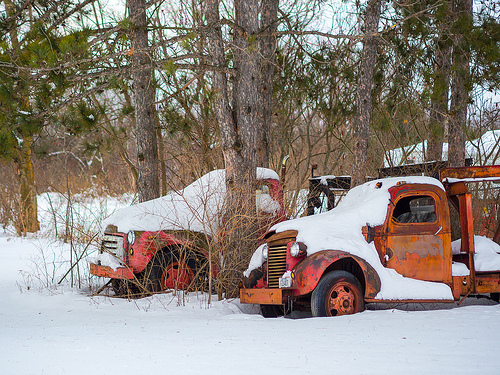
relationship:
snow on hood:
[0, 131, 499, 374] [91, 177, 289, 289]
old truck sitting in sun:
[238, 165, 500, 318] [73, 314, 408, 373]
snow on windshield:
[0, 131, 499, 374] [340, 189, 387, 223]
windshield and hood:
[340, 189, 387, 223] [264, 212, 369, 239]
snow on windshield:
[0, 131, 499, 374] [193, 179, 229, 206]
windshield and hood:
[193, 179, 229, 206] [285, 216, 332, 239]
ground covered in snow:
[118, 293, 228, 348] [209, 297, 285, 345]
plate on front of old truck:
[278, 277, 292, 288] [238, 165, 500, 318]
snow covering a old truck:
[0, 131, 499, 374] [238, 165, 500, 318]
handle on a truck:
[434, 224, 444, 239] [87, 167, 289, 314]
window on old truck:
[395, 194, 437, 229] [238, 165, 500, 318]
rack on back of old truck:
[441, 180, 496, 248] [238, 165, 500, 318]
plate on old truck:
[268, 270, 298, 287] [238, 165, 500, 318]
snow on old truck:
[0, 131, 499, 374] [238, 165, 500, 318]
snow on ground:
[0, 131, 499, 374] [0, 230, 498, 373]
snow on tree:
[17, 185, 147, 237] [0, 0, 235, 241]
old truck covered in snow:
[238, 165, 500, 318] [8, 320, 484, 370]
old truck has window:
[238, 165, 500, 318] [389, 189, 451, 227]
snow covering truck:
[0, 131, 499, 374] [227, 160, 498, 319]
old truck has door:
[238, 165, 500, 318] [388, 190, 448, 289]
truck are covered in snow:
[86, 156, 473, 300] [93, 163, 453, 308]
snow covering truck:
[0, 131, 499, 374] [102, 167, 282, 294]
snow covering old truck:
[0, 131, 499, 374] [238, 165, 500, 318]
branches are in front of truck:
[173, 202, 259, 300] [102, 167, 282, 294]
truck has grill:
[79, 167, 294, 303] [94, 229, 126, 273]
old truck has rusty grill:
[238, 165, 500, 318] [265, 240, 288, 288]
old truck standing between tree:
[238, 165, 500, 318] [202, 8, 273, 300]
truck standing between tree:
[86, 156, 473, 300] [202, 8, 273, 300]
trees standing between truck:
[0, 1, 499, 178] [90, 161, 348, 296]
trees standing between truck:
[0, 1, 499, 178] [227, 160, 498, 319]